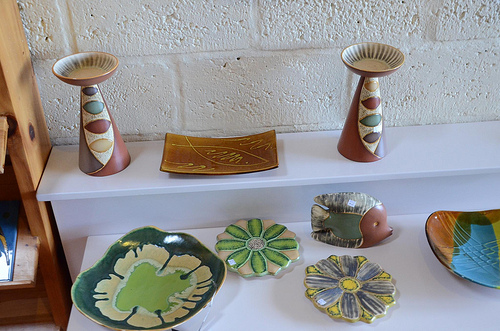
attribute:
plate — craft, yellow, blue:
[421, 200, 498, 307]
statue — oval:
[334, 37, 405, 171]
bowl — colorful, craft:
[424, 207, 499, 288]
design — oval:
[80, 97, 108, 114]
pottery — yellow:
[302, 251, 398, 326]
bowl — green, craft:
[71, 225, 226, 328]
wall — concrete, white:
[26, 6, 498, 125]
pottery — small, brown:
[151, 124, 286, 185]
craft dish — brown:
[162, 130, 277, 180]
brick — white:
[234, 30, 371, 135]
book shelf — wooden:
[2, 0, 71, 328]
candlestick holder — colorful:
[49, 49, 134, 177]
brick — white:
[183, 52, 337, 120]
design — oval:
[80, 85, 111, 166]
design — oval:
[362, 76, 384, 149]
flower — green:
[216, 218, 296, 277]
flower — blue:
[308, 249, 398, 318]